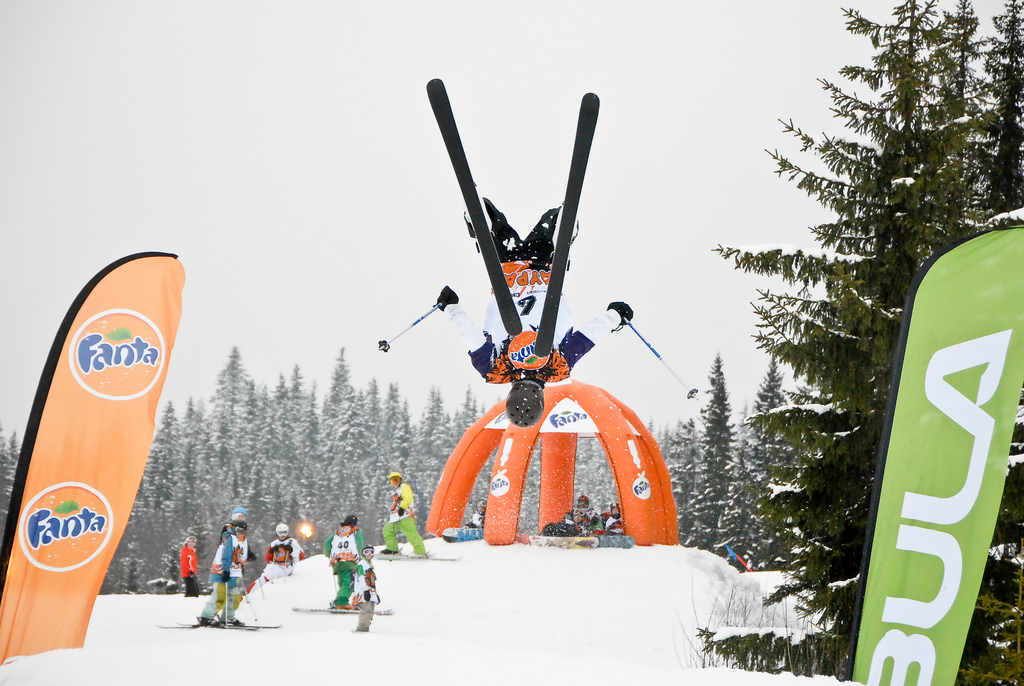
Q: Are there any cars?
A: No, there are no cars.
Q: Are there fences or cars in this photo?
A: No, there are no cars or fences.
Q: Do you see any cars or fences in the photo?
A: No, there are no cars or fences.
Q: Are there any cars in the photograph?
A: No, there are no cars.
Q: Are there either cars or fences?
A: No, there are no cars or fences.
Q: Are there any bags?
A: No, there are no bags.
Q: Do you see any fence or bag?
A: No, there are no bags or fences.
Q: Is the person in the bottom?
A: Yes, the person is in the bottom of the image.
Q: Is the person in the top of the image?
A: No, the person is in the bottom of the image.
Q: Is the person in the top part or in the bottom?
A: The person is in the bottom of the image.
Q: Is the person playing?
A: Yes, the person is playing.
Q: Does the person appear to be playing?
A: Yes, the person is playing.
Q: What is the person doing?
A: The person is playing.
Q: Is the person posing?
A: No, the person is playing.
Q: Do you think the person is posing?
A: No, the person is playing.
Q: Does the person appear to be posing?
A: No, the person is playing.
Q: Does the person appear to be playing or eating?
A: The person is playing.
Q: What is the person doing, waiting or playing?
A: The person is playing.